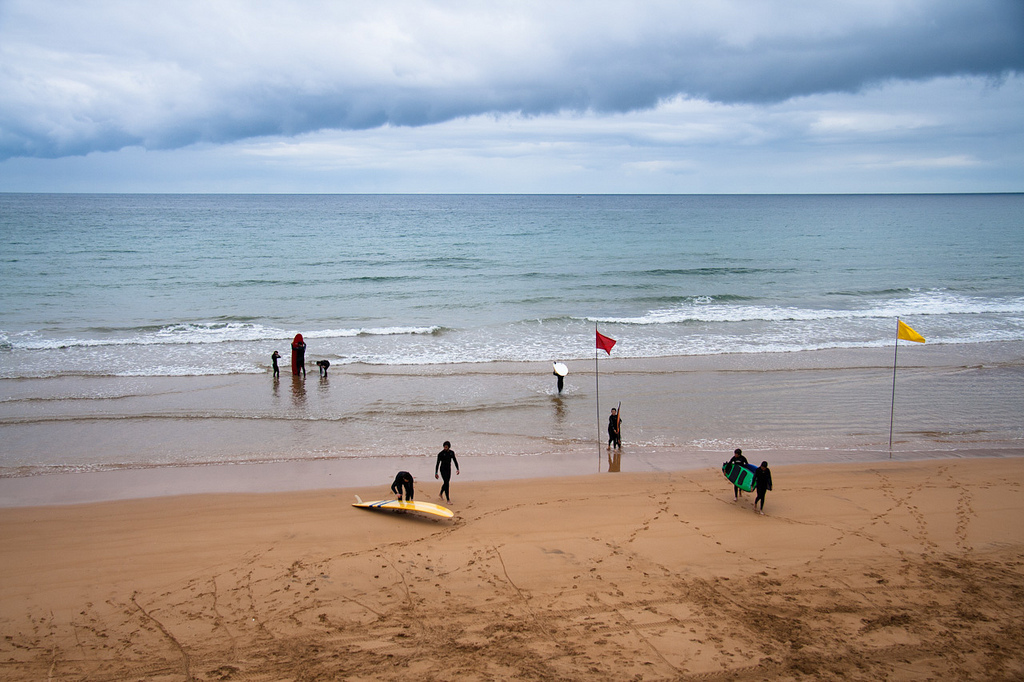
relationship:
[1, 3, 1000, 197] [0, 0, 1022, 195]
clouds in clouds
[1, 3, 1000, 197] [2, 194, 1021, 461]
clouds above water